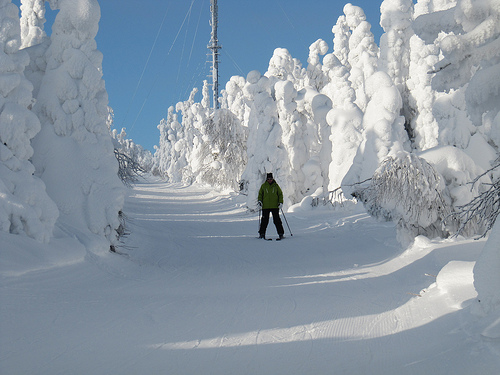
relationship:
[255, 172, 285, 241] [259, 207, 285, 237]
guy wearing pants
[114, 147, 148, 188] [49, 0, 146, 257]
branch hanging from tree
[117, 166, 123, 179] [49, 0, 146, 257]
branch hanging from tree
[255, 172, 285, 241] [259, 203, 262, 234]
guy holding ski pole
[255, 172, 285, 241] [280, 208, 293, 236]
guy holding poles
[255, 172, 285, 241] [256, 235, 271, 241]
guy standing on ski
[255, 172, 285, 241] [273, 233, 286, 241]
guy standing on ski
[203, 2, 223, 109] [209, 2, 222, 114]
ice covering pole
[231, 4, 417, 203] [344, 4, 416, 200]
sunlight shining on tree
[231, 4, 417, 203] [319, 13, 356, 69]
sunlight shining on tree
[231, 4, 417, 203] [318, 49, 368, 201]
sunlight shining on tree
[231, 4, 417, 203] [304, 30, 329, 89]
sunlight shining on tree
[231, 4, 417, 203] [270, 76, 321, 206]
sunlight shining on tree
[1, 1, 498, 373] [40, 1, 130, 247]
snow piled on tree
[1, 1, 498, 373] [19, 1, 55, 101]
snow piled on tree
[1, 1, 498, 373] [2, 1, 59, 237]
snow piled on tree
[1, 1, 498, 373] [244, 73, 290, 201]
snow covering tree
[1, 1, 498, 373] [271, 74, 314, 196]
snow covering tree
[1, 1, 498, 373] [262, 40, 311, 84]
snow covering tree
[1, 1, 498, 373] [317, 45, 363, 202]
snow covering tree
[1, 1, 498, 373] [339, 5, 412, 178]
snow covering tree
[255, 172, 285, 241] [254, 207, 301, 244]
guy wearing pants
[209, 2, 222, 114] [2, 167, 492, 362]
pole standing in snow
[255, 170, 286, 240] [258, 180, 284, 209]
guy wearing coat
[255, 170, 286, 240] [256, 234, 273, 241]
guy standing on ski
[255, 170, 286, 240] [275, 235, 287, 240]
guy standing on ski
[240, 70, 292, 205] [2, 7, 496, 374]
tree lining path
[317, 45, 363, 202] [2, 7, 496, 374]
tree lining path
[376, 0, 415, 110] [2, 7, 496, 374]
tree lining path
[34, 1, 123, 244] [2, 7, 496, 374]
tree lining path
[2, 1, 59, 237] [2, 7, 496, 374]
tree lining path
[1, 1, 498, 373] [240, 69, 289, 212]
snow covering tree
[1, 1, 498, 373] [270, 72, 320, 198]
snow covering tree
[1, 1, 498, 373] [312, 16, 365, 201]
snow covering tree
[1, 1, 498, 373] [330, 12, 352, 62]
snow covering tree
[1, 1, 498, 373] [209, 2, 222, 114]
snow covering pole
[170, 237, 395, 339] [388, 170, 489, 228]
shadows covered trees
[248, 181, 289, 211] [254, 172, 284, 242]
coat on skier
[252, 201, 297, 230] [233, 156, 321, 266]
poles in person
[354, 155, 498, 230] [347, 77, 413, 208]
branches from a tree